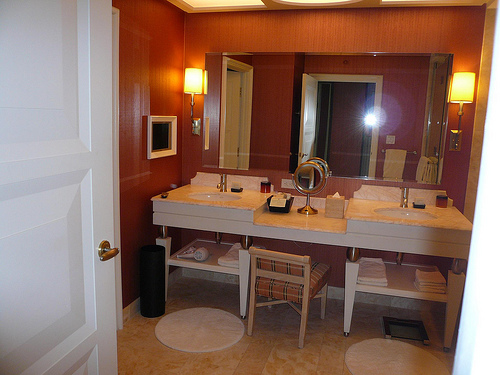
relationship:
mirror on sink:
[200, 47, 461, 177] [190, 176, 261, 217]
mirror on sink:
[290, 147, 342, 217] [166, 158, 461, 230]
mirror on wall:
[200, 47, 453, 189] [359, 22, 447, 46]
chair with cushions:
[241, 242, 331, 352] [257, 255, 305, 277]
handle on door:
[69, 224, 135, 284] [27, 105, 112, 178]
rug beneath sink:
[152, 306, 244, 356] [192, 183, 238, 208]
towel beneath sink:
[356, 256, 389, 288] [376, 208, 440, 219]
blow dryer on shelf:
[178, 246, 209, 263] [168, 238, 238, 279]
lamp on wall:
[439, 66, 473, 154] [118, 6, 488, 306]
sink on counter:
[370, 201, 437, 223] [152, 165, 466, 255]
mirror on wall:
[200, 47, 453, 189] [188, 7, 483, 52]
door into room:
[0, 2, 119, 372] [106, 0, 491, 374]